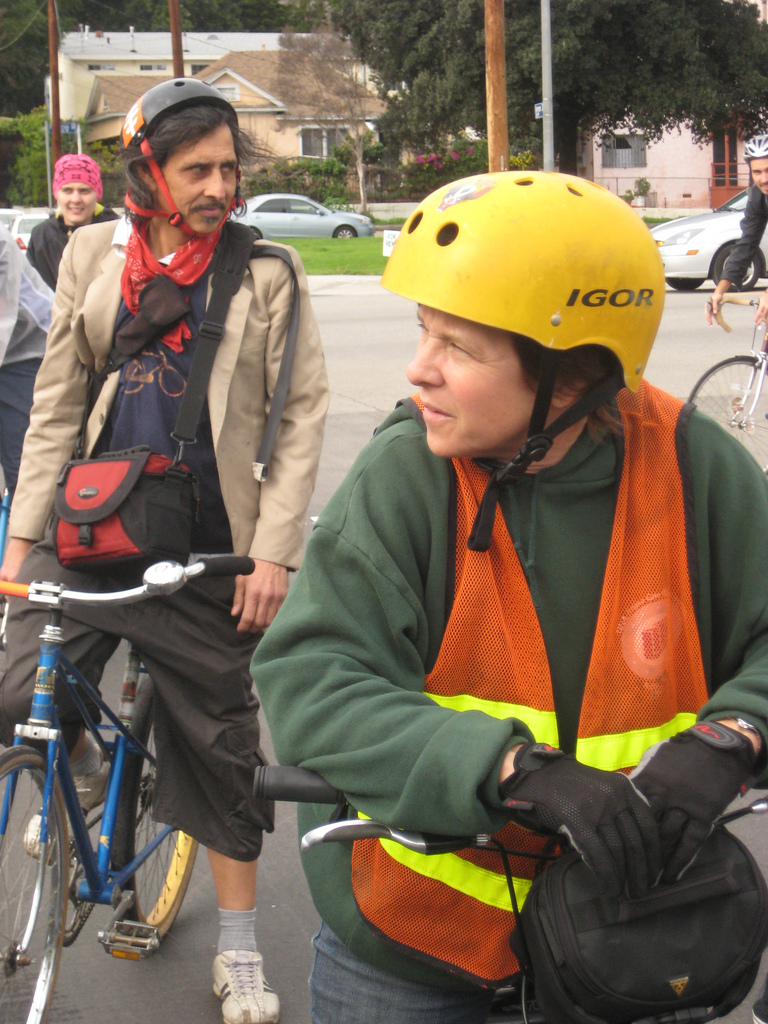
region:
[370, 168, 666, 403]
man wearing a yellow helmet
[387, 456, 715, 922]
man wearing a orange safety vest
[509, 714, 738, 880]
man wearing black gloves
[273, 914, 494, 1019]
man wearing blue jeans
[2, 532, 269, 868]
man wearing grey shorts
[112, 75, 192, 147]
man wearing black helmet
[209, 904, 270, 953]
man wearing gray socks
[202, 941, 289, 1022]
man wearing white shoes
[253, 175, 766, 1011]
person wearing yellow bike helmet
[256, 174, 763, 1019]
person wearing reflective safety vest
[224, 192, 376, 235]
grey vehicle parked near curbside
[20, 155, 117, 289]
woman wearing a pink hat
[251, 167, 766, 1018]
person holding a black bag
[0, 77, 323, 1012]
man wearing tan suit jacket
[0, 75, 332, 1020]
man sitting on a blue bike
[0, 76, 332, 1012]
man wearing red scarf around neck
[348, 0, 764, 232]
huge tree growing in background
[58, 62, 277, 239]
the man is looking to the side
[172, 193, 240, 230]
the man has a mustache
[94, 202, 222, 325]
the scarf is red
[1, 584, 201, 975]
the bike is blue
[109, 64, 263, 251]
the helmet is black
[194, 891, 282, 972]
the sock is grey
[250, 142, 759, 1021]
the person riding the bicycle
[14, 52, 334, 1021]
the person riding the bicycle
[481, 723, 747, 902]
the gloves are black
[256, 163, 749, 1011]
the person holding the bag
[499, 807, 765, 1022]
the bag is black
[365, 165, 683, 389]
the helmet on the head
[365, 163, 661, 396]
the helmet is yellow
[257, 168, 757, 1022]
the person wearing the safety vest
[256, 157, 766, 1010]
the person leaning on the handlebars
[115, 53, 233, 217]
face of the person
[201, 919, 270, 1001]
shoe of the man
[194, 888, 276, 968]
socks of the man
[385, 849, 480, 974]
a view of jacket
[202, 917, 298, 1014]
lace on the shoe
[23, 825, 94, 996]
a view of tire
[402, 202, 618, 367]
a view of helmet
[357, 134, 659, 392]
a helmet on head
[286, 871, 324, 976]
a view of road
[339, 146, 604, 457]
the head of a man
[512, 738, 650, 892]
the left hand of a man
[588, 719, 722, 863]
the right hand of a man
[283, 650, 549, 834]
the arm of a man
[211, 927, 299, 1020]
the shoe of a man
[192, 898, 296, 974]
the sock of a man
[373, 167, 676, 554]
a yellow and black helmet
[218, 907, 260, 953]
a man's gray sock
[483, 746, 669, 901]
a black glove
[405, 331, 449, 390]
the nose of a man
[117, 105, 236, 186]
short cut black hair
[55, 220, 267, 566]
a red and black bag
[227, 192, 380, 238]
the side of a car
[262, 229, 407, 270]
a green section of grass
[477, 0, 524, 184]
a tall brown pole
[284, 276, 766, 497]
a paved road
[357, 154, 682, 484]
Yellow helmet on person's head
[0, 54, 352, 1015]
A man sitting on a bicycle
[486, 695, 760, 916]
A pair of black gloves